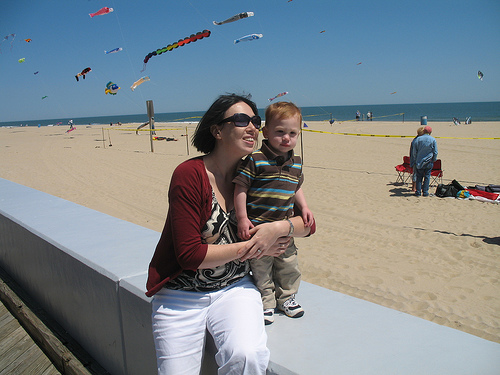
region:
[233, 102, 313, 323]
The little boy has red hair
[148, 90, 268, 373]
The lady is wearing black sunglasses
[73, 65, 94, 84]
A kite in the sky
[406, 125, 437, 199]
Two people standing on the beach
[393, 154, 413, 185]
Red foldable chair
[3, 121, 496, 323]
A brown sandy beach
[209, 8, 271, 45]
Kites are flying in the sky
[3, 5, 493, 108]
The sky is filled with kites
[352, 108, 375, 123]
People in the distant standing on the beach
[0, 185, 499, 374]
A wide concrete wall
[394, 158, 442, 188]
red lawn chairs sitting in sand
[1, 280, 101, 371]
boardwalk along beach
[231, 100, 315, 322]
child standing on concrete wall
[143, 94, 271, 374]
woman sitting on concrete wall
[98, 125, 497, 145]
yellow caution tape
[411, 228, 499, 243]
shadow on sand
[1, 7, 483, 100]
kite flying in wind above beach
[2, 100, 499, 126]
blue water in ocean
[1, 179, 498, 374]
grey concrete wall along boardwalk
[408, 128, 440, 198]
two people standing on beach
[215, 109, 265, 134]
dark black sunglasses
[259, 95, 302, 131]
a boy's brown hair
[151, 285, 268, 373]
a woman's white pants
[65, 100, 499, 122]
a large body of water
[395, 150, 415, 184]
a red chair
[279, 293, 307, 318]
a boy's tennis shoe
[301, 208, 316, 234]
the hand of a boy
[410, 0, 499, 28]
part of a blue sky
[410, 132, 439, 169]
a man's long sleeve blue shirt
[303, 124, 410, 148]
a long yellow line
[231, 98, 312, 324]
the small child fully dressed at the beach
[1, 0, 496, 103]
the multiple kites in the sky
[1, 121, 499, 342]
the sand at the beach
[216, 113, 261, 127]
the sunglasses on the woman's face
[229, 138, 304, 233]
the short sleeved shirt on the small child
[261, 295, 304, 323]
the shoes on the feet of the small child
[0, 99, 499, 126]
the large body of water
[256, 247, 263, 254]
the ring on the lady's finger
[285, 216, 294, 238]
the object on the lady's wrist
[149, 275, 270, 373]
the white pants on the woman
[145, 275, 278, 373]
Woman is wearing pants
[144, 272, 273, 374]
Woman is wearing white pants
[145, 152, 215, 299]
Woman is wearing a sweater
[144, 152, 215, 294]
Woman is wearing a brown sweater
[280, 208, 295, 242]
Woman is wearing a bracelet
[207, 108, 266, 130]
Woman is wearing sunglasses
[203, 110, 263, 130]
Woman is wearing black sunglasses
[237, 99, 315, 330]
Woman is holding onto a child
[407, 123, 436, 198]
People standing in sand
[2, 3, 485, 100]
Kites are being flown